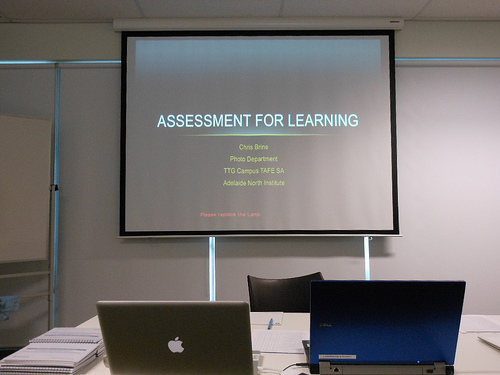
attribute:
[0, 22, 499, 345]
wall — WHITE, CLEAN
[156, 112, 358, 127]
writing — BOLD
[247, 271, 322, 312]
chair — BLACK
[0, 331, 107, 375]
book — open